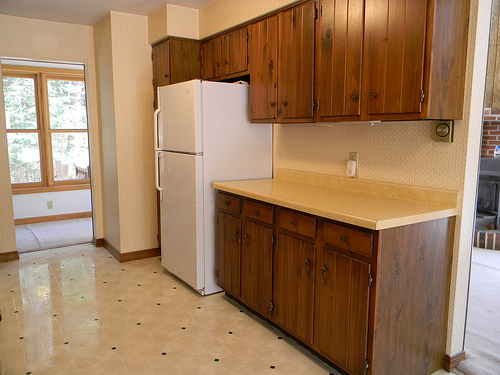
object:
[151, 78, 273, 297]
refrigerator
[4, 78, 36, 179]
tree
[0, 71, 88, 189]
window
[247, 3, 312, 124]
cabinet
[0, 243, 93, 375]
floor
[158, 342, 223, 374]
pattern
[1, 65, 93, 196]
frame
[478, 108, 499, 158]
wall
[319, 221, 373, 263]
drawer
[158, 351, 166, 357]
mark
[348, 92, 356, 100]
handle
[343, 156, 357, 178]
outlet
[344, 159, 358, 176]
air freshener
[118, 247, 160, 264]
trimming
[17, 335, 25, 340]
part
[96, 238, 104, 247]
part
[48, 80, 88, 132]
part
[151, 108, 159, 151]
part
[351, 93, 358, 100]
part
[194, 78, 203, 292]
edge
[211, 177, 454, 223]
surface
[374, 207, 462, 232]
edge